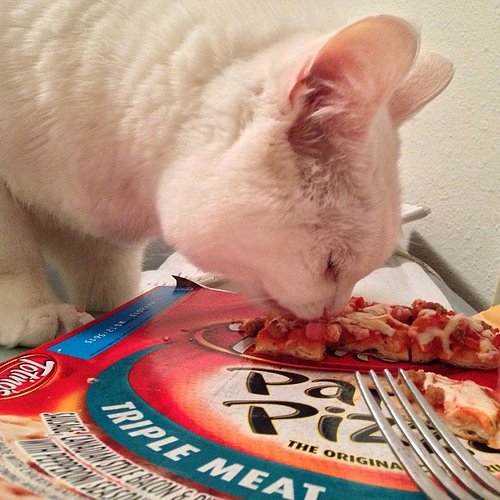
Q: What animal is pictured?
A: A cat.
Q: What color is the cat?
A: White.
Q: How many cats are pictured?
A: One.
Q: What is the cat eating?
A: Pizza.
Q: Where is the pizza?
A: On a box.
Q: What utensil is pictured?
A: A fork.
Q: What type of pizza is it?
A: Triple meat.